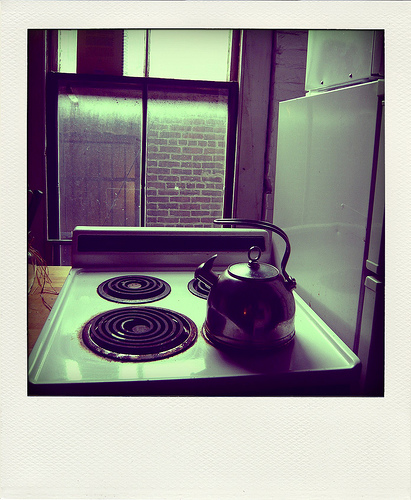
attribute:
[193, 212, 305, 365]
kettle — tea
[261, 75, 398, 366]
fridge — white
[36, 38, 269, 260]
window — small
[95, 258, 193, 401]
burners — bigger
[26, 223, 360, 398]
stove — black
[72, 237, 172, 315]
stove — black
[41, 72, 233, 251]
building — brick